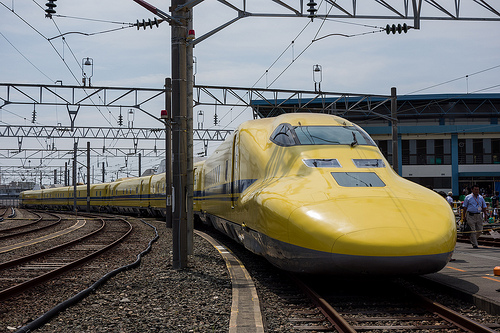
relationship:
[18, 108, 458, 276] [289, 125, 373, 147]
train has windshield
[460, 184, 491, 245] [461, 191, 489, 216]
man wearing shirt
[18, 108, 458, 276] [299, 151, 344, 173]
train has front light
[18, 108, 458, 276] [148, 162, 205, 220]
train has rear car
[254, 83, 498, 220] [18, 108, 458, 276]
building behind train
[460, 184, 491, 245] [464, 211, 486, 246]
man wearing pants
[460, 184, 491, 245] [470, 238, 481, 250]
man has shoe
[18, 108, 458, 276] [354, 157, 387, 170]
train has front light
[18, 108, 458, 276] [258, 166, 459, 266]
train has nose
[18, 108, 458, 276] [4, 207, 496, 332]
train on tracks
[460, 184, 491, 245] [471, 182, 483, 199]
man has head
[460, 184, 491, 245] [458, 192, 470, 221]
man has arm